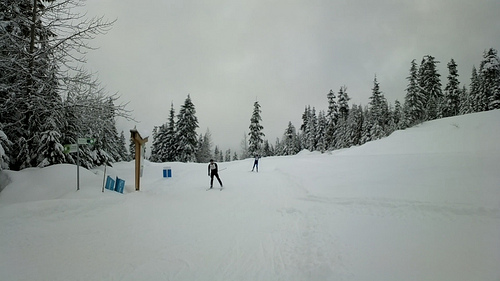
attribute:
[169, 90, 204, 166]
tree — full, spiky, tall, far, close, green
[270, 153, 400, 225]
snow — deep, white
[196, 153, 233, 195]
person — white, standing, still, skiing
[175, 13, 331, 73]
sky — close, overcast, dark, grey, white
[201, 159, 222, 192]
clothing — dark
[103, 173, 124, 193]
objects — blue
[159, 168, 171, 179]
objects — blue